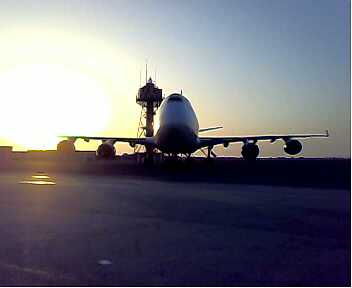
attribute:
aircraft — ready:
[56, 94, 329, 163]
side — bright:
[248, 89, 350, 123]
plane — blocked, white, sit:
[55, 94, 330, 165]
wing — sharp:
[198, 130, 331, 161]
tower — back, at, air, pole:
[134, 63, 164, 168]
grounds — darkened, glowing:
[1, 172, 349, 287]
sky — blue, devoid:
[0, 0, 349, 157]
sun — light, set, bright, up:
[21, 132, 59, 152]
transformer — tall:
[137, 61, 158, 165]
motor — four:
[238, 141, 264, 162]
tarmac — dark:
[2, 155, 351, 286]